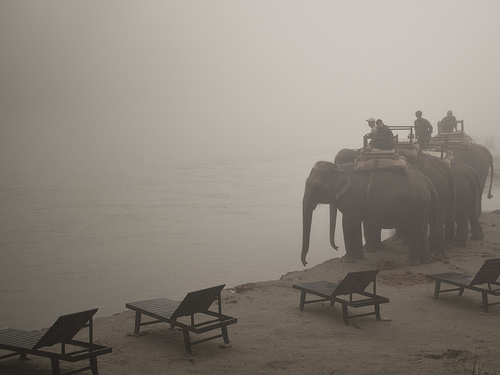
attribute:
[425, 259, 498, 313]
beach chair — wooden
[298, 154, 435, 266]
elephant — big